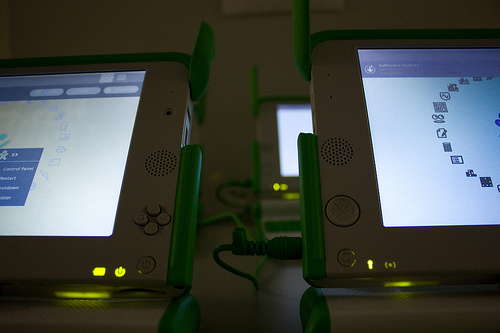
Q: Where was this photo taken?
A: Office.